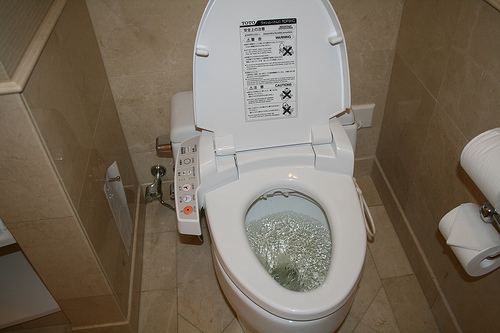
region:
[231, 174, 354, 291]
A toilet bowl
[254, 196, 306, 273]
A toilet bowl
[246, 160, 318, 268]
A toilet bowl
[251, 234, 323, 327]
A toilet bowl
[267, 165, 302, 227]
A toilet bowl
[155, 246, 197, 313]
this is the floor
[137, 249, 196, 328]
the floor is made of tiles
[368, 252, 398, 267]
the tile is cream in color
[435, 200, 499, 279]
this is a tissue paper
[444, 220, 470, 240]
the paper is white in color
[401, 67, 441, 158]
this is the wall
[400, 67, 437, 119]
the wall is made of tiles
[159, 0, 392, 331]
this is a toilet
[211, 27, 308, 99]
this is the toilet lid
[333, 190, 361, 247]
the seat is white in color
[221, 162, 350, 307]
this is a toilet sink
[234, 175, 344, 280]
the lid is open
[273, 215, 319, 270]
the inner has water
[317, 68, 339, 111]
this is the lid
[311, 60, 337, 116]
the lid is white in color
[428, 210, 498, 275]
this is a tissue paper roll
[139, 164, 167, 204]
this is a pipe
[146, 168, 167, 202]
the pipe is metallic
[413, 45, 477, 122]
the wall is tiled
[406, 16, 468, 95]
the wall is brown in color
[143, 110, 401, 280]
the bowl is hitech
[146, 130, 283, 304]
the bowl is hitech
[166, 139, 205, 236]
ELECTRONIC CONTROLS FOR TOILET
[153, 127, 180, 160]
MANUAL CONTROL OF THE TOILET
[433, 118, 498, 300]
TWO ROLLS OF TOILET PAPER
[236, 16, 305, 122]
INSTRUCTIONS FOR USE OF TOILET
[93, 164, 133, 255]
SANITARY NAPKIN DISPOSAL BAG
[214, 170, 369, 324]
TOILET HAS BEEN FLUSHED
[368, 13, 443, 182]
BROWN CERAMIC TILES ON THE WALLS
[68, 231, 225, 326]
FLOOR IS BROWN CERAMIC TILES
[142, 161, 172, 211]
WATER VALVE TO REGULATE FLOW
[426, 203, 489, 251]
END OF TOILET PAPER IS SHAPED INTO A TRIANGLE